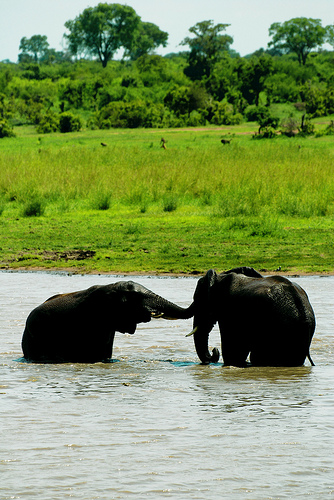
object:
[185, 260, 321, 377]
elephant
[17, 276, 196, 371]
elephant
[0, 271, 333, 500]
water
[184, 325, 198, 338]
tusk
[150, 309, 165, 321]
tusk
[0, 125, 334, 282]
grass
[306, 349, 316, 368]
tail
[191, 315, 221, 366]
trunk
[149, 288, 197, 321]
trunk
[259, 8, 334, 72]
trees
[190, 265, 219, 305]
ear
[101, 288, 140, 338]
ear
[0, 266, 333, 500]
river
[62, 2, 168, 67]
tree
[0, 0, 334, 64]
sky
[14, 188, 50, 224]
brush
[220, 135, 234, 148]
animals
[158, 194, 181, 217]
tufts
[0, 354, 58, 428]
waves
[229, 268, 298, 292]
back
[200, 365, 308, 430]
wave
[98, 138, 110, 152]
gazelle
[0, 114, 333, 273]
field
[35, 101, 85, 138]
bushes